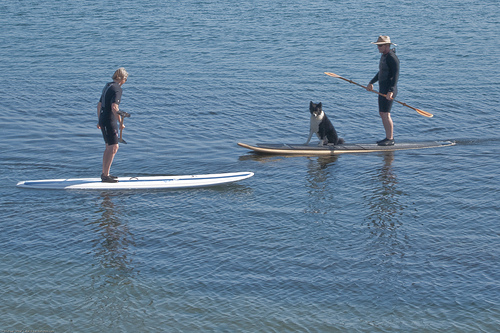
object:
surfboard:
[235, 132, 467, 156]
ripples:
[81, 260, 175, 302]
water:
[0, 0, 500, 331]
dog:
[305, 101, 345, 151]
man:
[367, 33, 402, 149]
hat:
[372, 34, 394, 49]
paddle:
[322, 69, 429, 122]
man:
[97, 66, 134, 186]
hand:
[367, 82, 374, 90]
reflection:
[98, 193, 140, 283]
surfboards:
[18, 170, 255, 192]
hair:
[112, 67, 130, 81]